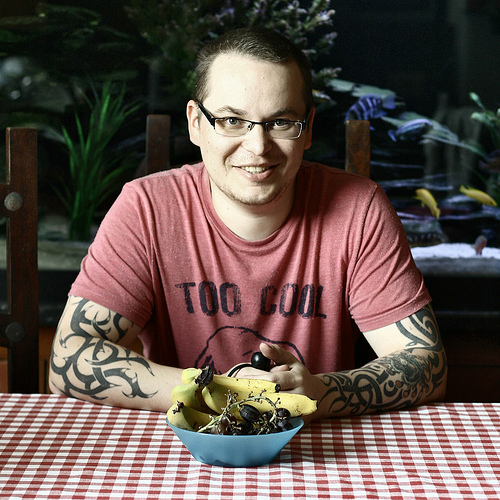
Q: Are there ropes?
A: No, there are no ropes.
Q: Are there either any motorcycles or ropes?
A: No, there are no ropes or motorcycles.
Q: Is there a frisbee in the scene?
A: No, there are no frisbees.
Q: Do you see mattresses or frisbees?
A: No, there are no frisbees or mattresses.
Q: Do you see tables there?
A: Yes, there is a table.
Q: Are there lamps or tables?
A: Yes, there is a table.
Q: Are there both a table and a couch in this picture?
A: No, there is a table but no couches.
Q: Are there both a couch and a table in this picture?
A: No, there is a table but no couches.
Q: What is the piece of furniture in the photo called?
A: The piece of furniture is a table.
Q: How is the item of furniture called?
A: The piece of furniture is a table.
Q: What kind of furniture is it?
A: The piece of furniture is a table.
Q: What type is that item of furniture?
A: This is a table.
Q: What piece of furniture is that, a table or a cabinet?
A: This is a table.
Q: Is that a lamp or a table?
A: That is a table.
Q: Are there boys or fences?
A: No, there are no boys or fences.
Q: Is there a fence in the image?
A: No, there are no fences.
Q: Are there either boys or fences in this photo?
A: No, there are no fences or boys.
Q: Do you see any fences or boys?
A: No, there are no fences or boys.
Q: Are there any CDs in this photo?
A: No, there are no cds.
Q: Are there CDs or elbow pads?
A: No, there are no CDs or elbow pads.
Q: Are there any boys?
A: No, there are no boys.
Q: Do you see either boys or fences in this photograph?
A: No, there are no boys or fences.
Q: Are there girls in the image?
A: No, there are no girls.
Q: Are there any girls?
A: No, there are no girls.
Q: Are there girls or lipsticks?
A: No, there are no girls or lipsticks.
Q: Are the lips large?
A: Yes, the lips are large.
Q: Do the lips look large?
A: Yes, the lips are large.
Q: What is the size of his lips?
A: The lips are large.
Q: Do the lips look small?
A: No, the lips are large.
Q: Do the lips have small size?
A: No, the lips are large.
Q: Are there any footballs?
A: No, there are no footballs.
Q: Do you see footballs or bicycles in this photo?
A: No, there are no footballs or bicycles.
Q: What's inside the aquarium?
A: The fish is inside the aquarium.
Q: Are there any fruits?
A: Yes, there is a fruit.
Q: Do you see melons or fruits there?
A: Yes, there is a fruit.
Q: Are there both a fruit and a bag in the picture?
A: No, there is a fruit but no bags.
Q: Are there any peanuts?
A: No, there are no peanuts.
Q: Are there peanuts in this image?
A: No, there are no peanuts.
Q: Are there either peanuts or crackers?
A: No, there are no peanuts or crackers.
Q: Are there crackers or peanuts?
A: No, there are no peanuts or crackers.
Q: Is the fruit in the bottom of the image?
A: Yes, the fruit is in the bottom of the image.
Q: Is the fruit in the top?
A: No, the fruit is in the bottom of the image.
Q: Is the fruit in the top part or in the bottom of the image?
A: The fruit is in the bottom of the image.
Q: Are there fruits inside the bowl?
A: Yes, there is a fruit inside the bowl.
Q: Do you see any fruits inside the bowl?
A: Yes, there is a fruit inside the bowl.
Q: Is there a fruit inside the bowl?
A: Yes, there is a fruit inside the bowl.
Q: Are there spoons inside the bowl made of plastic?
A: No, there is a fruit inside the bowl.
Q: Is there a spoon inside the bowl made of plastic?
A: No, there is a fruit inside the bowl.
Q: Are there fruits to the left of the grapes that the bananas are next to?
A: Yes, there is a fruit to the left of the grapes.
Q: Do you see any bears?
A: No, there are no bears.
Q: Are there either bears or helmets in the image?
A: No, there are no bears or helmets.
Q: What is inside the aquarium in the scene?
A: The fish is inside the aquarium.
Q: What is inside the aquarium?
A: The fish is inside the aquarium.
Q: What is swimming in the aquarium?
A: The fish is swimming in the aquarium.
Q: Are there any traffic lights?
A: No, there are no traffic lights.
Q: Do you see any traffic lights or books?
A: No, there are no traffic lights or books.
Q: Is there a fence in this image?
A: No, there are no fences.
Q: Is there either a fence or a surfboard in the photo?
A: No, there are no fences or surfboards.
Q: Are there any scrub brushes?
A: No, there are no scrub brushes.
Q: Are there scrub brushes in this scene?
A: No, there are no scrub brushes.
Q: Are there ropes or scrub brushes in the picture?
A: No, there are no scrub brushes or ropes.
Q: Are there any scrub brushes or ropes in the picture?
A: No, there are no scrub brushes or ropes.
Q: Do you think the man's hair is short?
A: Yes, the hair is short.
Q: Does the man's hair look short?
A: Yes, the hair is short.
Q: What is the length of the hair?
A: The hair is short.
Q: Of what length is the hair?
A: The hair is short.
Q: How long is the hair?
A: The hair is short.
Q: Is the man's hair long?
A: No, the hair is short.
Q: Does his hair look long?
A: No, the hair is short.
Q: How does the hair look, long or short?
A: The hair is short.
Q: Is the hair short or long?
A: The hair is short.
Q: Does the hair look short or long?
A: The hair is short.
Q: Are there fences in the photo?
A: No, there are no fences.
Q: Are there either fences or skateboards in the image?
A: No, there are no fences or skateboards.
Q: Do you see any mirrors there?
A: No, there are no mirrors.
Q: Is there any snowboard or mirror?
A: No, there are no mirrors or snowboards.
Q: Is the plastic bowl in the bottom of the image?
A: Yes, the bowl is in the bottom of the image.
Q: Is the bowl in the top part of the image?
A: No, the bowl is in the bottom of the image.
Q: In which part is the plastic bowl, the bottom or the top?
A: The bowl is in the bottom of the image.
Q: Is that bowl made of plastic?
A: Yes, the bowl is made of plastic.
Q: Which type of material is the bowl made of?
A: The bowl is made of plastic.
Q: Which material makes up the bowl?
A: The bowl is made of plastic.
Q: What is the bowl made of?
A: The bowl is made of plastic.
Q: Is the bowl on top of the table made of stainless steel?
A: No, the bowl is made of plastic.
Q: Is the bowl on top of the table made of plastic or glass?
A: The bowl is made of plastic.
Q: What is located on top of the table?
A: The bowl is on top of the table.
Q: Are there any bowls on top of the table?
A: Yes, there is a bowl on top of the table.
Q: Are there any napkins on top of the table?
A: No, there is a bowl on top of the table.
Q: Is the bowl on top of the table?
A: Yes, the bowl is on top of the table.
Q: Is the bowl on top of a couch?
A: No, the bowl is on top of the table.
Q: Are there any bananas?
A: Yes, there are bananas.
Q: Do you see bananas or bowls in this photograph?
A: Yes, there are bananas.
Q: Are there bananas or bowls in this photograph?
A: Yes, there are bananas.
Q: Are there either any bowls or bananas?
A: Yes, there are bananas.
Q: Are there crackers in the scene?
A: No, there are no crackers.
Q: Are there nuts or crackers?
A: No, there are no crackers or nuts.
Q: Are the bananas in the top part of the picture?
A: No, the bananas are in the bottom of the image.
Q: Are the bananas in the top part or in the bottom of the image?
A: The bananas are in the bottom of the image.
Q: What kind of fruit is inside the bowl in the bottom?
A: The fruits are bananas.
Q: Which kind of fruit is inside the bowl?
A: The fruits are bananas.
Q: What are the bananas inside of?
A: The bananas are inside the bowl.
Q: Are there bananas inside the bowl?
A: Yes, there are bananas inside the bowl.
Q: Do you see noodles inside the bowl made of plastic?
A: No, there are bananas inside the bowl.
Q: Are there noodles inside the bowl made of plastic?
A: No, there are bananas inside the bowl.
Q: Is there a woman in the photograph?
A: No, there are no women.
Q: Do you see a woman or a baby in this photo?
A: No, there are no women or babies.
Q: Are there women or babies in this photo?
A: No, there are no women or babies.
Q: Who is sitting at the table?
A: The man is sitting at the table.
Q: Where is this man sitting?
A: The man is sitting at the table.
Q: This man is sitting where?
A: The man is sitting at the table.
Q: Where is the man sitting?
A: The man is sitting at the table.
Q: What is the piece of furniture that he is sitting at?
A: The piece of furniture is a table.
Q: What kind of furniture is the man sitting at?
A: The man is sitting at the table.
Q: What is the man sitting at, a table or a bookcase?
A: The man is sitting at a table.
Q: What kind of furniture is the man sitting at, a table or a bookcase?
A: The man is sitting at a table.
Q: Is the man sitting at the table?
A: Yes, the man is sitting at the table.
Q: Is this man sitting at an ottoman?
A: No, the man is sitting at the table.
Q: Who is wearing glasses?
A: The man is wearing glasses.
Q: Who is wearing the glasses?
A: The man is wearing glasses.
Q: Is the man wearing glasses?
A: Yes, the man is wearing glasses.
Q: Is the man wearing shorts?
A: No, the man is wearing glasses.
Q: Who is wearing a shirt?
A: The man is wearing a shirt.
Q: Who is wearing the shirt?
A: The man is wearing a shirt.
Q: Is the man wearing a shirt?
A: Yes, the man is wearing a shirt.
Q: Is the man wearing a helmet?
A: No, the man is wearing a shirt.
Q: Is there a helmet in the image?
A: No, there are no helmets.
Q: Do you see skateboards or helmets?
A: No, there are no helmets or skateboards.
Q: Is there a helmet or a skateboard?
A: No, there are no helmets or skateboards.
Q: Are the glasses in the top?
A: Yes, the glasses are in the top of the image.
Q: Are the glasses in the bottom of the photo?
A: No, the glasses are in the top of the image.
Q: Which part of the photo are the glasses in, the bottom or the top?
A: The glasses are in the top of the image.